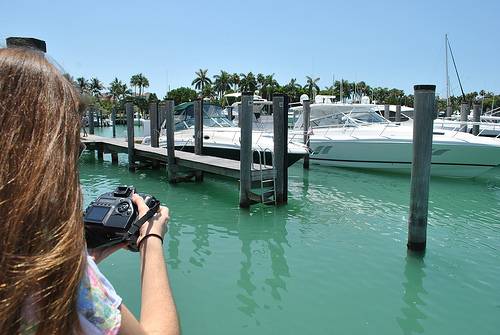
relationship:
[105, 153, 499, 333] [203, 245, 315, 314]
water has ripples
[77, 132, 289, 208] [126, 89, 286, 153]
dock with posts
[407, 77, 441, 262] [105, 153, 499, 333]
post in water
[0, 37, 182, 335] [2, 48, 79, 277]
girl has hair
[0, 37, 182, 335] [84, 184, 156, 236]
girl has camera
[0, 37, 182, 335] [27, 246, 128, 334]
girl has shirt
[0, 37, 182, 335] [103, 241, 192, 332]
girl has arm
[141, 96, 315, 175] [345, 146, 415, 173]
boat with stripe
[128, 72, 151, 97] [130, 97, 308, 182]
palm trees behind boats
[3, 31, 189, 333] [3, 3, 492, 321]
girl taking photo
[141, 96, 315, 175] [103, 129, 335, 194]
boat in dock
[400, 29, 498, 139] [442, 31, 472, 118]
sailboat has mast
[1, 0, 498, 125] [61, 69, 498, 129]
distance has trees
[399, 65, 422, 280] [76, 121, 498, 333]
pillars are in water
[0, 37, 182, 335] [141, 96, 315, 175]
girl photographing boat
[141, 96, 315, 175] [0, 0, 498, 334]
boat are in harbor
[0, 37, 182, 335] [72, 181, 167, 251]
girl has camera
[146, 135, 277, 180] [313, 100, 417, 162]
dock has boat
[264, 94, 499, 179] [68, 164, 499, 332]
boat in water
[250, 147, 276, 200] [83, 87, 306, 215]
ladder attached to dock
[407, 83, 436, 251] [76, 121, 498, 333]
post sticking out of water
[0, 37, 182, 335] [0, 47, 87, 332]
girl has hair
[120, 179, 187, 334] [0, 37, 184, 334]
arm on photographer's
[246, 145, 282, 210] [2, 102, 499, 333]
stairs coming from water